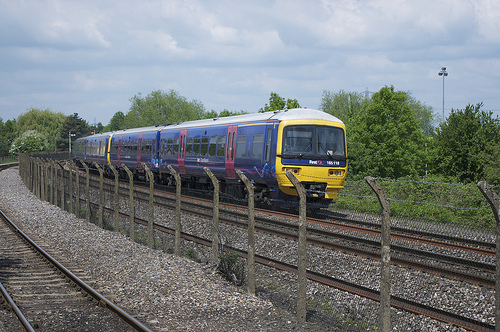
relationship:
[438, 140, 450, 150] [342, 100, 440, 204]
leaves of tree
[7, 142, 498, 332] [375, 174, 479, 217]
fencing with barbwire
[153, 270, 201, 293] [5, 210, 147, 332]
stones lining tracks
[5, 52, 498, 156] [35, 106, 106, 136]
skies above clouds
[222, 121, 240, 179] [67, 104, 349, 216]
doors for train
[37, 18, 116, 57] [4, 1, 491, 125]
clouds in a sky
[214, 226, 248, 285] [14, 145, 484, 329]
weeds growing along line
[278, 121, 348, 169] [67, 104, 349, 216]
windshield of train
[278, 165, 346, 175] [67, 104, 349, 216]
headlights of train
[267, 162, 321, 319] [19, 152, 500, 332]
post for fencing